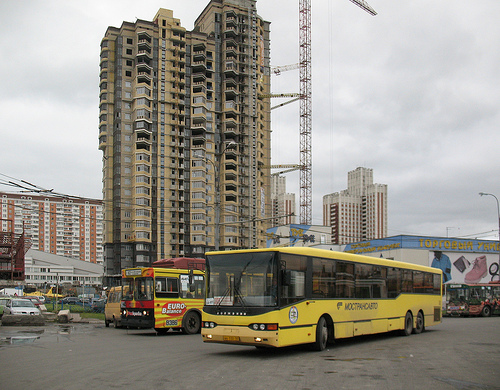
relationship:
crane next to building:
[353, 0, 380, 16] [99, 2, 271, 307]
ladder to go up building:
[250, 9, 258, 251] [99, 2, 271, 307]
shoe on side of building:
[465, 257, 488, 284] [310, 235, 500, 285]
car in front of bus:
[3, 299, 39, 323] [200, 247, 444, 352]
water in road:
[0, 324, 46, 344] [1, 315, 498, 389]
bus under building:
[200, 247, 444, 352] [99, 2, 271, 307]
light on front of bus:
[254, 337, 261, 342] [200, 247, 444, 352]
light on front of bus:
[207, 334, 211, 340] [200, 247, 444, 352]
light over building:
[476, 192, 486, 196] [310, 235, 500, 285]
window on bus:
[311, 258, 336, 297] [200, 247, 444, 352]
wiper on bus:
[214, 275, 232, 310] [200, 247, 444, 352]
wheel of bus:
[405, 310, 413, 333] [200, 247, 444, 352]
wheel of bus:
[316, 316, 332, 350] [200, 247, 444, 352]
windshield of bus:
[203, 252, 280, 308] [200, 247, 444, 352]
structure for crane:
[261, 0, 312, 244] [353, 0, 380, 16]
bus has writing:
[200, 247, 444, 352] [342, 301, 379, 311]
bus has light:
[200, 247, 444, 352] [254, 337, 261, 342]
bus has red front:
[122, 257, 205, 333] [120, 268, 157, 333]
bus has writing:
[122, 257, 205, 333] [161, 302, 184, 315]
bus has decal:
[122, 257, 205, 333] [159, 297, 188, 316]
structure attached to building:
[261, 0, 312, 244] [99, 2, 271, 307]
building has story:
[99, 2, 271, 307] [99, 75, 270, 95]